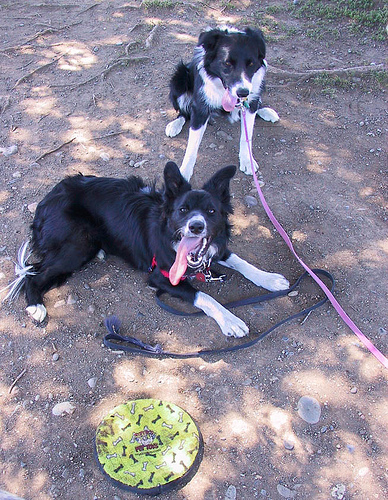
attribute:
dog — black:
[1, 161, 290, 339]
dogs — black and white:
[45, 28, 350, 312]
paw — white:
[208, 302, 251, 339]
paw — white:
[246, 267, 290, 292]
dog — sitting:
[147, 25, 303, 177]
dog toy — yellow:
[84, 390, 204, 497]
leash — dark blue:
[220, 94, 386, 387]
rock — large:
[52, 401, 77, 416]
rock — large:
[297, 394, 321, 423]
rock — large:
[222, 485, 241, 498]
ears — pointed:
[156, 156, 239, 200]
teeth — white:
[188, 237, 209, 266]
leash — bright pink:
[240, 109, 386, 363]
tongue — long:
[222, 91, 235, 108]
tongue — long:
[173, 237, 198, 279]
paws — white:
[194, 253, 289, 337]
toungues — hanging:
[168, 82, 240, 283]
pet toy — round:
[93, 397, 200, 487]